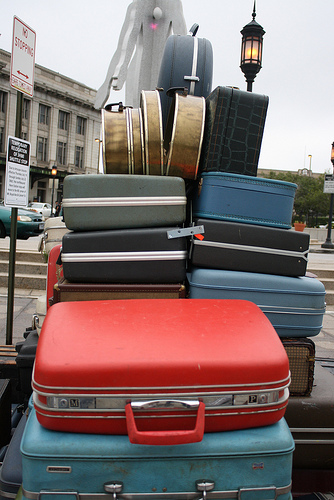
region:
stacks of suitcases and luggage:
[11, 25, 323, 498]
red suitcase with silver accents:
[29, 300, 296, 440]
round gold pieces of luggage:
[95, 79, 206, 177]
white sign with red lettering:
[8, 17, 40, 98]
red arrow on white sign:
[14, 68, 29, 79]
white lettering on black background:
[9, 137, 31, 162]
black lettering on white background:
[7, 166, 29, 201]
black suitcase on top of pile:
[158, 21, 212, 100]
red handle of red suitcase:
[120, 401, 212, 445]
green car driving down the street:
[2, 199, 40, 243]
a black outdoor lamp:
[240, 0, 265, 93]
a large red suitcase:
[29, 295, 298, 445]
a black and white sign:
[5, 134, 34, 209]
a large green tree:
[268, 169, 332, 215]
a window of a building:
[38, 104, 49, 123]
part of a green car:
[0, 202, 40, 238]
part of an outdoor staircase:
[2, 248, 50, 285]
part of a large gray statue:
[94, 0, 183, 109]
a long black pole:
[6, 206, 22, 343]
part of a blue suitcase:
[19, 408, 296, 499]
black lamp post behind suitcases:
[236, 0, 267, 92]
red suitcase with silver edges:
[31, 296, 293, 446]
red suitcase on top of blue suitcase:
[29, 297, 292, 445]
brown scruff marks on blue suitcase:
[91, 453, 272, 489]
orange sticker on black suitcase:
[195, 229, 205, 240]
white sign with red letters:
[12, 12, 36, 98]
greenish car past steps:
[0, 203, 47, 239]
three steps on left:
[0, 246, 47, 288]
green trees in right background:
[259, 170, 333, 226]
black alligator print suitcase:
[200, 80, 270, 178]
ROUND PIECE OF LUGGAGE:
[92, 99, 132, 172]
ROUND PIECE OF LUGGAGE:
[130, 110, 149, 172]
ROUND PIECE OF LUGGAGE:
[143, 80, 171, 182]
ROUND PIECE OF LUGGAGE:
[172, 111, 200, 178]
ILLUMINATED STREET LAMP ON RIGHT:
[226, 1, 280, 89]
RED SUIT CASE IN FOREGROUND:
[43, 301, 263, 413]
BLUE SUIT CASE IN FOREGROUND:
[50, 431, 268, 498]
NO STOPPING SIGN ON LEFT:
[18, 19, 46, 96]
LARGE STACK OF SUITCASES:
[75, 82, 325, 497]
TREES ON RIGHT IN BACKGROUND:
[269, 160, 328, 231]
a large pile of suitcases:
[0, 22, 328, 498]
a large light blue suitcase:
[8, 420, 300, 497]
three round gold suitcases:
[85, 74, 217, 183]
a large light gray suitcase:
[43, 142, 193, 238]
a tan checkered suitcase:
[279, 340, 324, 399]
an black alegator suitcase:
[203, 83, 271, 177]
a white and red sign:
[10, 12, 52, 101]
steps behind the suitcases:
[0, 240, 64, 309]